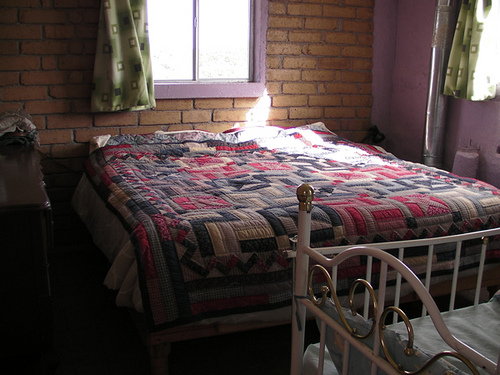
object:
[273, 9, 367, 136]
wall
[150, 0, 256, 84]
window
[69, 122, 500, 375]
bed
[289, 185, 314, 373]
post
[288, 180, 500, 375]
bed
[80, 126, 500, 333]
quilt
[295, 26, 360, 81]
brick